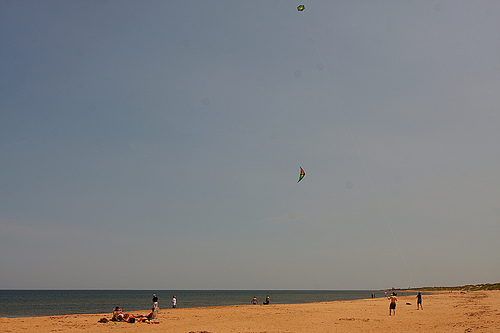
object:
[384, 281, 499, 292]
grassy hill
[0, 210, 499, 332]
coastal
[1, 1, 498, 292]
blue sky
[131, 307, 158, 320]
person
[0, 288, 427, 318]
water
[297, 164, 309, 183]
kite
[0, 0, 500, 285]
sky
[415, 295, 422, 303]
shirt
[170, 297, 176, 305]
shirt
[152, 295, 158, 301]
shirt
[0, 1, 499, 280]
clouds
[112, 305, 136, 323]
person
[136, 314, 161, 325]
person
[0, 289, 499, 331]
sand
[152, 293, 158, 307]
person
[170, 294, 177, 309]
person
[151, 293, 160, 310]
people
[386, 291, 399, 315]
man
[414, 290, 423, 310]
people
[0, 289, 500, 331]
beach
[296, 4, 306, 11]
kite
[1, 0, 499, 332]
air